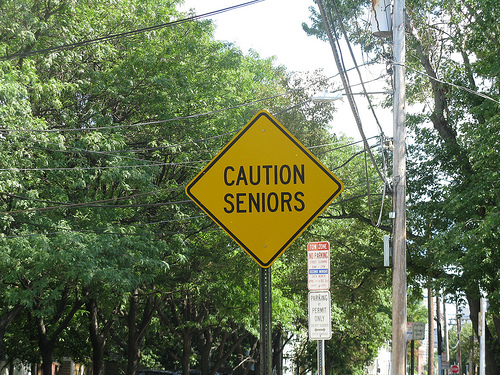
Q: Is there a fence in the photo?
A: No, there are no fences.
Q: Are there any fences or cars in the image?
A: No, there are no fences or cars.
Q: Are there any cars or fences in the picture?
A: No, there are no fences or cars.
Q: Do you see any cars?
A: No, there are no cars.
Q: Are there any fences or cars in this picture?
A: No, there are no cars or fences.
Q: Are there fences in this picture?
A: No, there are no fences.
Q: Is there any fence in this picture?
A: No, there are no fences.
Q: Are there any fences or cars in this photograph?
A: No, there are no fences or cars.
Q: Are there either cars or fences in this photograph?
A: No, there are no fences or cars.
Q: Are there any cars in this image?
A: No, there are no cars.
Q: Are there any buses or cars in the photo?
A: No, there are no cars or buses.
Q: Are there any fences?
A: No, there are no fences.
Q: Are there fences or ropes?
A: No, there are no fences or ropes.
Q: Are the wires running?
A: Yes, the wires are running.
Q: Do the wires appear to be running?
A: Yes, the wires are running.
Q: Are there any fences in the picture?
A: No, there are no fences.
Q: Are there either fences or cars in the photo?
A: No, there are no fences or cars.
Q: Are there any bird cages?
A: No, there are no bird cages.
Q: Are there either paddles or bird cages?
A: No, there are no bird cages or paddles.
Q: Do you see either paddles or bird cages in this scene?
A: No, there are no bird cages or paddles.